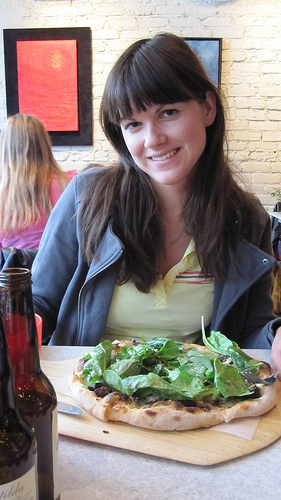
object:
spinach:
[212, 352, 256, 398]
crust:
[69, 337, 276, 435]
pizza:
[68, 336, 277, 431]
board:
[40, 345, 281, 469]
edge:
[56, 400, 82, 410]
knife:
[54, 399, 84, 417]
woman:
[27, 28, 281, 372]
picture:
[14, 35, 82, 140]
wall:
[1, 0, 281, 219]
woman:
[0, 110, 79, 256]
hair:
[1, 111, 67, 229]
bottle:
[0, 265, 59, 499]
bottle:
[0, 318, 38, 499]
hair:
[74, 33, 250, 296]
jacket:
[29, 166, 280, 352]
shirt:
[98, 230, 215, 346]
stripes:
[170, 275, 214, 285]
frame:
[4, 26, 94, 148]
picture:
[182, 36, 222, 94]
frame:
[176, 36, 222, 93]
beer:
[16, 384, 60, 498]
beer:
[1, 406, 43, 500]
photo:
[1, 0, 281, 499]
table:
[36, 346, 281, 498]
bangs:
[108, 53, 193, 121]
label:
[52, 399, 64, 500]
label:
[0, 463, 38, 498]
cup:
[3, 311, 44, 390]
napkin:
[57, 363, 263, 442]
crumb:
[100, 428, 111, 436]